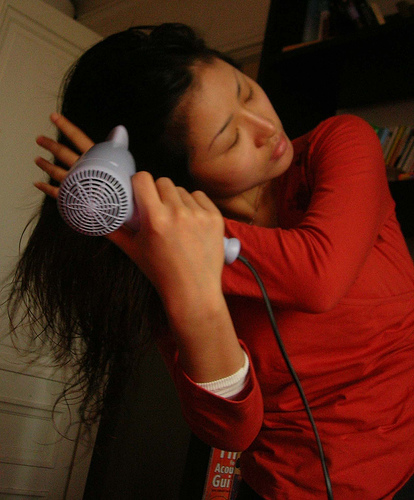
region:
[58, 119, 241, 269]
girl holding a gray hair dryer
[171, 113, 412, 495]
girl wearing a red shirt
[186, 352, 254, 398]
white shirt under a red shirt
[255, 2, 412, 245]
books in a bookcase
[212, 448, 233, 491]
blue lettering on a red book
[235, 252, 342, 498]
hairdryer's black electrical cord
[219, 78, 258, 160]
girl with her eyes closed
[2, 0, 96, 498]
open white door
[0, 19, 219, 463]
girl with long black hair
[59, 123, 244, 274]
hairdryer in a girl's hand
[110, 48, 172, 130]
Woman has black hair.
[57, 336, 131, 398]
Woman has long hair.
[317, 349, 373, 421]
Woman wearing red shirt.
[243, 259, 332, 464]
Black cord on blow dryer.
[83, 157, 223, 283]
Woman holding gray blow dryer.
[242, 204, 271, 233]
Silver necklace around woman's neck.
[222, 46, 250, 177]
Woman has black eyebrows.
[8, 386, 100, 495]
White drawers behind woman.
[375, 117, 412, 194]
Books on black book shelf.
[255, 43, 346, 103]
Black bookshelf near wall.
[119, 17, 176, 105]
hair of a lady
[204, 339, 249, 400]
part of a hand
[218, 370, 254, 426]
edge of a sleev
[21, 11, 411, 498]
This is a brown lady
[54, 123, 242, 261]
a gray hair dryer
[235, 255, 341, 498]
a long black cord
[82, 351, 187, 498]
part of a black bookcase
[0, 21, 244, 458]
a woman's long black hair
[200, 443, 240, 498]
part of a red and white book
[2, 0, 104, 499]
part of a white door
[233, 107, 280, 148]
the nose of a woman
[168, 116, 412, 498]
a woman's red shirt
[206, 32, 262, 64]
part of a white door trim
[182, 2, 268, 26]
part of a white wall